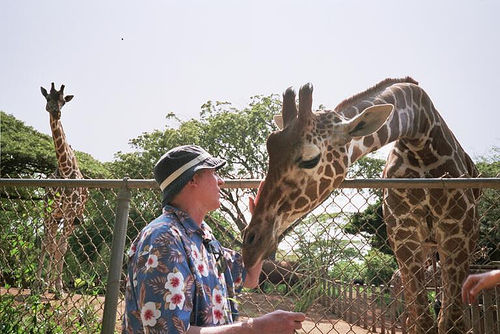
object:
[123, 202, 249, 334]
floral shirt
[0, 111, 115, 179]
tree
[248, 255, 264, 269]
mouth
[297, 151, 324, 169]
eye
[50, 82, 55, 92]
horns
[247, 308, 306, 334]
hand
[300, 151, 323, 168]
eyelashes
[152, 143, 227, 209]
hat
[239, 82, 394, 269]
giraffe's head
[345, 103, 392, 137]
ear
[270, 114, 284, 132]
ear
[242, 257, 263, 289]
tongue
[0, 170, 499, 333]
fence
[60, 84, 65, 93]
horn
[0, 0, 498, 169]
sky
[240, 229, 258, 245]
giraffe's nose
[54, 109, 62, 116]
giraffe's nose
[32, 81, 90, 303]
giraffe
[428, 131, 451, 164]
spot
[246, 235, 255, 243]
nose holes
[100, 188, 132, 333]
pole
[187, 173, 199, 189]
ear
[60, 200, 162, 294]
trees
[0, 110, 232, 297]
hills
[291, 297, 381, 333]
dirt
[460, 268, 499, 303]
hand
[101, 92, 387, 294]
tree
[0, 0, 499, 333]
background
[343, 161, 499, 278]
trees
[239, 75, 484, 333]
giraffe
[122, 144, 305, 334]
man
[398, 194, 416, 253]
spots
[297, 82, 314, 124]
horn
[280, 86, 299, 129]
horn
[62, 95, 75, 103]
ear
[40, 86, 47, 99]
ear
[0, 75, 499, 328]
enclosure